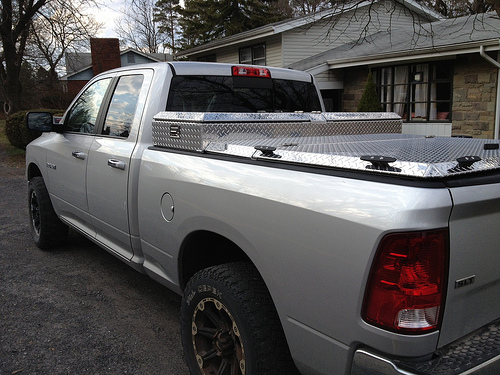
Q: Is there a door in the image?
A: Yes, there is a door.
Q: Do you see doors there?
A: Yes, there is a door.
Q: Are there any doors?
A: Yes, there is a door.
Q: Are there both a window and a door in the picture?
A: Yes, there are both a door and a window.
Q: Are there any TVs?
A: No, there are no tvs.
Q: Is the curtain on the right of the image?
A: Yes, the curtain is on the right of the image.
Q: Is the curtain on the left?
A: No, the curtain is on the right of the image.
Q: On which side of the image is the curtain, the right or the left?
A: The curtain is on the right of the image.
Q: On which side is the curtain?
A: The curtain is on the right of the image.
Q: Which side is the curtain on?
A: The curtain is on the right of the image.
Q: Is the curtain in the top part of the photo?
A: Yes, the curtain is in the top of the image.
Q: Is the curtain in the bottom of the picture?
A: No, the curtain is in the top of the image.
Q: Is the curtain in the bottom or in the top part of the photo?
A: The curtain is in the top of the image.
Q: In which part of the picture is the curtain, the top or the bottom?
A: The curtain is in the top of the image.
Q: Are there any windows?
A: Yes, there is a window.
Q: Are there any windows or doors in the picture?
A: Yes, there is a window.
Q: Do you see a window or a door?
A: Yes, there is a window.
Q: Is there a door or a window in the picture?
A: Yes, there is a window.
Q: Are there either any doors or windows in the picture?
A: Yes, there is a window.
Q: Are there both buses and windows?
A: No, there is a window but no buses.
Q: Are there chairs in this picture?
A: No, there are no chairs.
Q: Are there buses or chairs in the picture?
A: No, there are no chairs or buses.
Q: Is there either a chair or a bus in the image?
A: No, there are no chairs or buses.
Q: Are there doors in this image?
A: Yes, there is a door.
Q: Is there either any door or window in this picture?
A: Yes, there is a door.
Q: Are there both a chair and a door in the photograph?
A: No, there is a door but no chairs.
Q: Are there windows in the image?
A: Yes, there is a window.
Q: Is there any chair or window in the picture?
A: Yes, there is a window.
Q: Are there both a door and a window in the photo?
A: Yes, there are both a window and a door.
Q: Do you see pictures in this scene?
A: No, there are no pictures.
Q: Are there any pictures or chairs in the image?
A: No, there are no pictures or chairs.